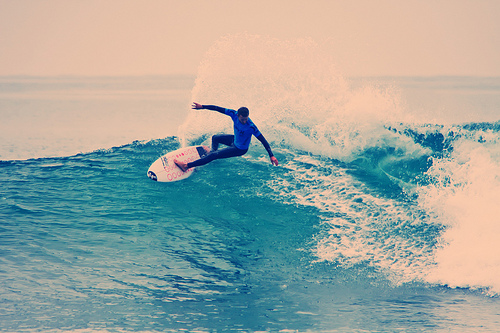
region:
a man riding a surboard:
[153, 112, 291, 184]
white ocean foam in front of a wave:
[303, 182, 446, 300]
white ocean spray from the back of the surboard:
[195, 33, 377, 125]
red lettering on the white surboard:
[166, 166, 200, 179]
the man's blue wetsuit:
[196, 114, 266, 171]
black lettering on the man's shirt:
[231, 125, 247, 139]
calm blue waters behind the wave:
[42, 73, 155, 125]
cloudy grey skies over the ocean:
[187, 20, 372, 49]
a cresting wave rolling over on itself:
[304, 117, 496, 219]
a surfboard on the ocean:
[133, 138, 222, 184]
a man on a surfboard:
[131, 99, 292, 192]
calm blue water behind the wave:
[48, 98, 134, 134]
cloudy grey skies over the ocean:
[56, 1, 173, 66]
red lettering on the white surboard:
[166, 168, 181, 181]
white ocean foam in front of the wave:
[305, 173, 406, 293]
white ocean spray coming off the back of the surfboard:
[208, 50, 358, 106]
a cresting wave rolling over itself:
[326, 107, 485, 229]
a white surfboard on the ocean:
[135, 150, 220, 192]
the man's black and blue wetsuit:
[189, 125, 271, 162]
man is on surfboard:
[146, 98, 261, 165]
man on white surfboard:
[117, 107, 262, 199]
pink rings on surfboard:
[135, 96, 234, 190]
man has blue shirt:
[230, 108, 254, 140]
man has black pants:
[179, 141, 251, 176]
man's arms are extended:
[196, 96, 273, 166]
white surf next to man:
[277, 120, 479, 332]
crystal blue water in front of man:
[13, 209, 165, 313]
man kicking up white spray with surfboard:
[170, 36, 322, 148]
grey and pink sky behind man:
[10, 3, 263, 83]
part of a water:
[183, 178, 237, 243]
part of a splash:
[403, 130, 447, 188]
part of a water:
[179, 235, 234, 297]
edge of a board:
[143, 155, 164, 180]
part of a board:
[163, 154, 175, 169]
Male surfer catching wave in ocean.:
[146, 101, 278, 183]